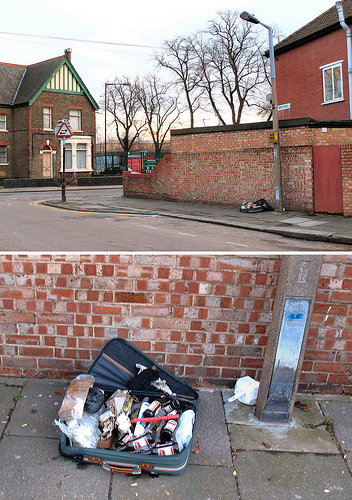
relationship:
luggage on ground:
[58, 337, 197, 475] [0, 372, 346, 498]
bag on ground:
[227, 374, 260, 405] [0, 379, 352, 500]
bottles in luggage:
[117, 390, 178, 455] [58, 335, 198, 475]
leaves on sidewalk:
[93, 202, 144, 208] [62, 196, 350, 255]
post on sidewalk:
[240, 10, 283, 212] [43, 187, 350, 242]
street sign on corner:
[49, 118, 76, 204] [38, 187, 105, 217]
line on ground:
[141, 222, 156, 232] [3, 185, 351, 251]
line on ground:
[176, 231, 197, 237] [3, 185, 351, 251]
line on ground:
[225, 239, 247, 248] [3, 185, 351, 251]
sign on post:
[266, 129, 280, 147] [240, 10, 285, 212]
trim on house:
[45, 54, 86, 93] [0, 43, 103, 179]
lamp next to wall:
[237, 10, 261, 27] [118, 141, 350, 217]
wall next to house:
[122, 117, 351, 216] [262, 0, 351, 120]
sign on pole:
[53, 121, 72, 139] [51, 116, 75, 207]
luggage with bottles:
[58, 337, 197, 475] [115, 393, 195, 455]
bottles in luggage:
[115, 393, 195, 455] [58, 337, 197, 475]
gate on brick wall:
[310, 144, 345, 218] [228, 158, 269, 182]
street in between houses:
[0, 184, 130, 205] [4, 27, 166, 211]